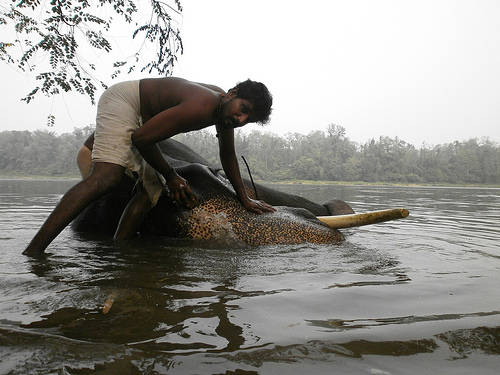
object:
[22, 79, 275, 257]
man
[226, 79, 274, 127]
hair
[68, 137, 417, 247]
elephant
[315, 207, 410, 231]
tusk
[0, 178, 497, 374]
water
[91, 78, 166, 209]
cloth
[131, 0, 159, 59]
branches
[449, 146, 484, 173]
trees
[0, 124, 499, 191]
distance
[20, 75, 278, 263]
dark skin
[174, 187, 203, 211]
bath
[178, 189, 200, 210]
sponge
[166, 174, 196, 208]
hand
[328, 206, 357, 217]
foot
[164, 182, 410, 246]
head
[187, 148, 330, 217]
leg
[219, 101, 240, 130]
beard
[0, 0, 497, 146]
sky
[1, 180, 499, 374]
brown